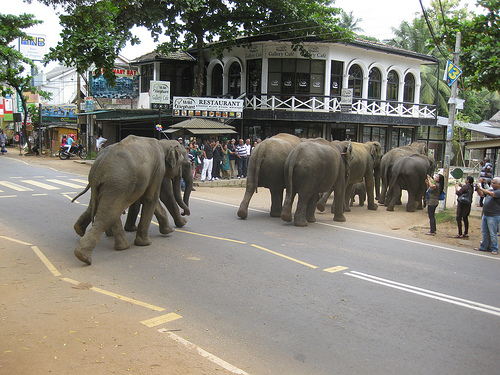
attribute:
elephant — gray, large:
[75, 135, 190, 266]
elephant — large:
[280, 141, 353, 228]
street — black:
[1, 155, 499, 374]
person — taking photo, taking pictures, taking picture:
[424, 173, 446, 235]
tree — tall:
[41, 2, 355, 101]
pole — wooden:
[76, 70, 82, 156]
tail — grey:
[71, 173, 97, 203]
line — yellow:
[326, 264, 347, 274]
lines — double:
[345, 270, 499, 318]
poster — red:
[87, 65, 141, 105]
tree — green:
[0, 13, 52, 156]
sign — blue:
[444, 65, 461, 86]